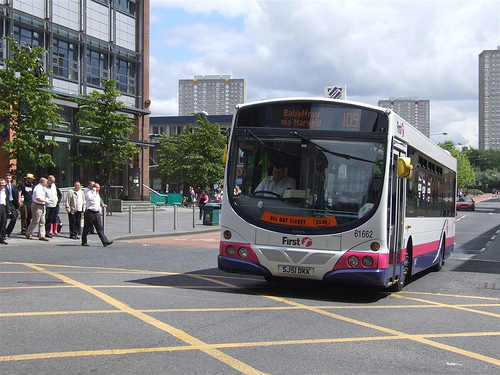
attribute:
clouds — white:
[239, 2, 424, 98]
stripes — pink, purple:
[331, 247, 386, 287]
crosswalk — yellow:
[44, 265, 361, 371]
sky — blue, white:
[149, 10, 498, 150]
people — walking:
[24, 163, 123, 249]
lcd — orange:
[277, 107, 359, 130]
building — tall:
[175, 76, 260, 119]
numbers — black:
[353, 227, 373, 240]